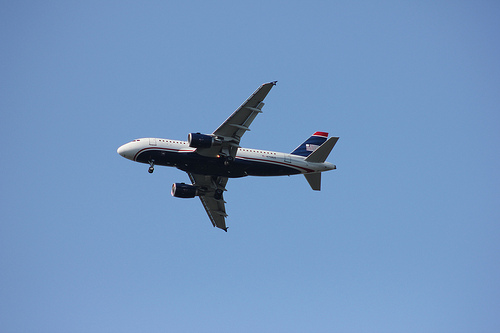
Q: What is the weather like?
A: It is clear.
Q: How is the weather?
A: It is clear.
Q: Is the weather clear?
A: Yes, it is clear.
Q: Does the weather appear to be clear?
A: Yes, it is clear.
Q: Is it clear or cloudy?
A: It is clear.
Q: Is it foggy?
A: No, it is clear.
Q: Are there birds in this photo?
A: No, there are no birds.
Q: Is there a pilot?
A: No, there are no pilots.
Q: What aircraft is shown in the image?
A: The aircraft is a jet.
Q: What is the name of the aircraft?
A: The aircraft is a jet.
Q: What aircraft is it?
A: The aircraft is a jet.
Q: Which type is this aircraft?
A: This is a jet.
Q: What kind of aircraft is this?
A: This is a jet.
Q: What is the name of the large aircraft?
A: The aircraft is a jet.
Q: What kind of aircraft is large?
A: The aircraft is a jet.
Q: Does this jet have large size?
A: Yes, the jet is large.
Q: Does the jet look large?
A: Yes, the jet is large.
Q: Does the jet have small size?
A: No, the jet is large.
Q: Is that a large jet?
A: Yes, that is a large jet.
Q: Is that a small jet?
A: No, that is a large jet.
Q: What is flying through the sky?
A: The jet is flying through the sky.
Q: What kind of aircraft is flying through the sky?
A: The aircraft is a jet.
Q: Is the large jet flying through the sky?
A: Yes, the jet is flying through the sky.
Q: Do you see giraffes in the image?
A: No, there are no giraffes.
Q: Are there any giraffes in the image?
A: No, there are no giraffes.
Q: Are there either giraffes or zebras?
A: No, there are no giraffes or zebras.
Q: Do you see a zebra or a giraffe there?
A: No, there are no giraffes or zebras.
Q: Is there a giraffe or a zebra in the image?
A: No, there are no giraffes or zebras.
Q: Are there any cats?
A: No, there are no cats.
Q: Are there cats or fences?
A: No, there are no cats or fences.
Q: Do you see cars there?
A: No, there are no cars.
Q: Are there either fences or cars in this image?
A: No, there are no cars or fences.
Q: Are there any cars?
A: No, there are no cars.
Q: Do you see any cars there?
A: No, there are no cars.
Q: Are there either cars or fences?
A: No, there are no cars or fences.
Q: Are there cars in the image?
A: No, there are no cars.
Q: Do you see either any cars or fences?
A: No, there are no cars or fences.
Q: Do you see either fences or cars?
A: No, there are no cars or fences.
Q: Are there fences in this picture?
A: No, there are no fences.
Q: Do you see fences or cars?
A: No, there are no fences or cars.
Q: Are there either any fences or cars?
A: No, there are no fences or cars.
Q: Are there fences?
A: No, there are no fences.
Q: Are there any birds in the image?
A: No, there are no birds.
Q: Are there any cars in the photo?
A: No, there are no cars.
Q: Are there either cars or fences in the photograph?
A: No, there are no cars or fences.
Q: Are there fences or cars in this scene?
A: No, there are no cars or fences.